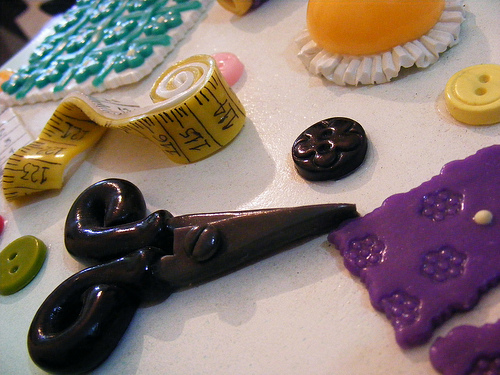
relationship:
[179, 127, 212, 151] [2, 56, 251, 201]
number on measuring tape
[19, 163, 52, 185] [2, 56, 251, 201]
number on measuring tape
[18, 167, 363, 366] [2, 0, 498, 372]
scissor on cake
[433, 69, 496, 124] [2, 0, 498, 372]
button on cake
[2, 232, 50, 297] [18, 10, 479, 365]
button on cake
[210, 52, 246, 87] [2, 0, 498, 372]
button on cake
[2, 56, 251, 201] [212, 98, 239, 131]
measuring tape has black letters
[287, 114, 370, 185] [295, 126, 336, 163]
circle with flower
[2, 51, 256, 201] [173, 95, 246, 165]
measuring tape with numbers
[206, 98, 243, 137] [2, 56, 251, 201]
number on measuring tape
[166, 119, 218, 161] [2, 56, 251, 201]
number on measuring tape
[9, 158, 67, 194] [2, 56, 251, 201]
number on measuring tape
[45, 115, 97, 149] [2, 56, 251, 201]
number on measuring tape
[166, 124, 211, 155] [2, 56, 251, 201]
number on measuring tape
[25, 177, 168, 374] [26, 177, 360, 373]
handle of scissors